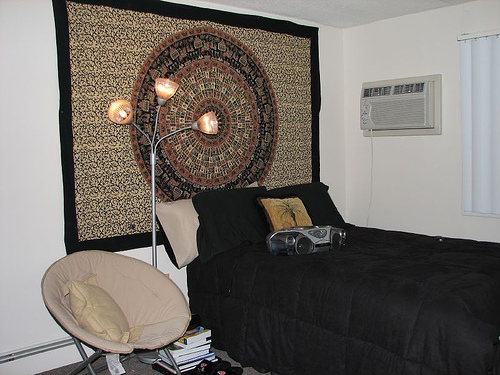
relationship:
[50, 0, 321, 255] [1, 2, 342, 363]
rug hanging on wall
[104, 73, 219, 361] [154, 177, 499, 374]
lamp next to bed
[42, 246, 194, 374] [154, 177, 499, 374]
chair next to bed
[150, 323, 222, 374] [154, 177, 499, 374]
books next to bed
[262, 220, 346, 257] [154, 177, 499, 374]
radio on top of bed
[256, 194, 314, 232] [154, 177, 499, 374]
pillow on top of bed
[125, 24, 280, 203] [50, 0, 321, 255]
design in center of rug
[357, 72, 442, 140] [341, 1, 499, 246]
air conditioner mounted on wall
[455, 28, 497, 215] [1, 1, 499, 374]
blinds inside of bedroom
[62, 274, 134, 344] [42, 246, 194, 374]
pillow on top of chair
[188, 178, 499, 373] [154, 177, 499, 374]
bedding on top of bed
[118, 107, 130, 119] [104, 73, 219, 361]
bulb on top of lamp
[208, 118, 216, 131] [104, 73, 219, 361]
bulb on top of lamp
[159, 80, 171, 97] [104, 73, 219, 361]
bulb on top of lamp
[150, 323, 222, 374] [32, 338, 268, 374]
books on top of floor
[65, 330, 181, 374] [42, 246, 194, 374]
legs on bottom of chair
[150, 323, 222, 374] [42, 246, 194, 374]
books to right of chair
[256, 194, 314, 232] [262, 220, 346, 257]
pillow behind radio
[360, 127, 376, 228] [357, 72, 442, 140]
cord hanging from air conditioner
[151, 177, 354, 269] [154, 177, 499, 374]
pillows on top of bed